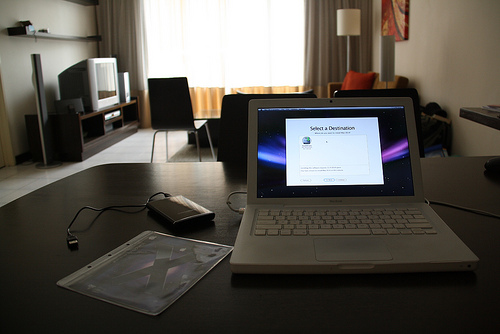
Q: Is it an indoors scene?
A: Yes, it is indoors.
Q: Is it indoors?
A: Yes, it is indoors.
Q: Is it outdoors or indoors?
A: It is indoors.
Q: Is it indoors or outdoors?
A: It is indoors.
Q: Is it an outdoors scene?
A: No, it is indoors.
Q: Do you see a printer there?
A: No, there are no printers.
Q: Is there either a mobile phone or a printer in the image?
A: No, there are no printers or cell phones.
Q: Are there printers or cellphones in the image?
A: No, there are no printers or cellphones.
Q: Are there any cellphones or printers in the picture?
A: No, there are no printers or cellphones.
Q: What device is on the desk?
A: The device is a hard drive.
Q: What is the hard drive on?
A: The hard drive is on the desk.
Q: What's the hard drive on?
A: The hard drive is on the desk.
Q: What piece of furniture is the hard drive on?
A: The hard drive is on the desk.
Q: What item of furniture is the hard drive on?
A: The hard drive is on the desk.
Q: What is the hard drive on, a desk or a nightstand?
A: The hard drive is on a desk.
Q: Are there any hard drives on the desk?
A: Yes, there is a hard drive on the desk.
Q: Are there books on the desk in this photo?
A: No, there is a hard drive on the desk.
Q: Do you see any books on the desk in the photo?
A: No, there is a hard drive on the desk.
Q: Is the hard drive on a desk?
A: Yes, the hard drive is on a desk.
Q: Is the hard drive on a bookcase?
A: No, the hard drive is on a desk.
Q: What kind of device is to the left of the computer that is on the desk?
A: The device is a hard drive.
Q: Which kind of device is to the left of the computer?
A: The device is a hard drive.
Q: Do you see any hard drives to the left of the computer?
A: Yes, there is a hard drive to the left of the computer.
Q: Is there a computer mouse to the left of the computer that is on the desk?
A: No, there is a hard drive to the left of the computer.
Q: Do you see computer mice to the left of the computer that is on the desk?
A: No, there is a hard drive to the left of the computer.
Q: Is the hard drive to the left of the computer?
A: Yes, the hard drive is to the left of the computer.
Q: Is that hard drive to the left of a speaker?
A: No, the hard drive is to the left of the computer.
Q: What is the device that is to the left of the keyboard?
A: The device is a hard drive.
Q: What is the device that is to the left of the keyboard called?
A: The device is a hard drive.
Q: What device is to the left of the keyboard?
A: The device is a hard drive.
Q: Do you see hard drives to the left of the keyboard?
A: Yes, there is a hard drive to the left of the keyboard.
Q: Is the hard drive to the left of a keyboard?
A: Yes, the hard drive is to the left of a keyboard.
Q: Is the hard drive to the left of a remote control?
A: No, the hard drive is to the left of a keyboard.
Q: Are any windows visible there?
A: Yes, there is a window.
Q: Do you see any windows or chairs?
A: Yes, there is a window.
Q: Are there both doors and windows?
A: No, there is a window but no doors.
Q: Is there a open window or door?
A: Yes, there is an open window.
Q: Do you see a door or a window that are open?
A: Yes, the window is open.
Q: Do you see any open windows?
A: Yes, there is an open window.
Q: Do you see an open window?
A: Yes, there is an open window.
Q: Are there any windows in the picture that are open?
A: Yes, there is a window that is open.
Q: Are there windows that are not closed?
A: Yes, there is a open window.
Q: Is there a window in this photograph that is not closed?
A: Yes, there is a open window.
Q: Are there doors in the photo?
A: No, there are no doors.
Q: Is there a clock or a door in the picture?
A: No, there are no doors or clocks.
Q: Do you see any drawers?
A: No, there are no drawers.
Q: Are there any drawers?
A: No, there are no drawers.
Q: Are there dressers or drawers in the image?
A: No, there are no drawers or dressers.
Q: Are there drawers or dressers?
A: No, there are no drawers or dressers.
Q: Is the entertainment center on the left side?
A: Yes, the entertainment center is on the left of the image.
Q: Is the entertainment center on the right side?
A: No, the entertainment center is on the left of the image.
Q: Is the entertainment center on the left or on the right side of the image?
A: The entertainment center is on the left of the image.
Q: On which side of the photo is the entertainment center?
A: The entertainment center is on the left of the image.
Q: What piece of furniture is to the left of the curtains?
A: The piece of furniture is an entertainment center.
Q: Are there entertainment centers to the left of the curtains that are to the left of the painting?
A: Yes, there is an entertainment center to the left of the curtains.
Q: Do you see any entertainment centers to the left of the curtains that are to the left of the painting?
A: Yes, there is an entertainment center to the left of the curtains.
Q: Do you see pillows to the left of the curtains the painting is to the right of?
A: No, there is an entertainment center to the left of the curtains.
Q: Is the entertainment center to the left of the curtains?
A: Yes, the entertainment center is to the left of the curtains.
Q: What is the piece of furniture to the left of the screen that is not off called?
A: The piece of furniture is an entertainment center.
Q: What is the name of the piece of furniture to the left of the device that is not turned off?
A: The piece of furniture is an entertainment center.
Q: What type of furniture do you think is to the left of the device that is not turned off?
A: The piece of furniture is an entertainment center.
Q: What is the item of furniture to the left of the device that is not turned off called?
A: The piece of furniture is an entertainment center.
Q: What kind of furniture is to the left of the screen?
A: The piece of furniture is an entertainment center.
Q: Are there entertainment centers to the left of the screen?
A: Yes, there is an entertainment center to the left of the screen.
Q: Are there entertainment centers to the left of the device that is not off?
A: Yes, there is an entertainment center to the left of the screen.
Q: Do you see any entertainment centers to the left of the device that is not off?
A: Yes, there is an entertainment center to the left of the screen.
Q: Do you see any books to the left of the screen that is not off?
A: No, there is an entertainment center to the left of the screen.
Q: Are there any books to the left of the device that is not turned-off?
A: No, there is an entertainment center to the left of the screen.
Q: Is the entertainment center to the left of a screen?
A: Yes, the entertainment center is to the left of a screen.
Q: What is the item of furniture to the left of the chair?
A: The piece of furniture is an entertainment center.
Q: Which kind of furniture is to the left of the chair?
A: The piece of furniture is an entertainment center.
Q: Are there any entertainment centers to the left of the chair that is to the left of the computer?
A: Yes, there is an entertainment center to the left of the chair.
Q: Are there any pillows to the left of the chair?
A: No, there is an entertainment center to the left of the chair.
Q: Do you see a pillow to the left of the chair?
A: No, there is an entertainment center to the left of the chair.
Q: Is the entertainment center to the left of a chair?
A: Yes, the entertainment center is to the left of a chair.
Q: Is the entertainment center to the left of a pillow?
A: No, the entertainment center is to the left of a chair.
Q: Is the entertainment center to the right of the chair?
A: No, the entertainment center is to the left of the chair.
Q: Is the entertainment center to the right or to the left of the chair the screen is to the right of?
A: The entertainment center is to the left of the chair.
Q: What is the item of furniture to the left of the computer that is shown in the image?
A: The piece of furniture is an entertainment center.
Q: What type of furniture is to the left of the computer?
A: The piece of furniture is an entertainment center.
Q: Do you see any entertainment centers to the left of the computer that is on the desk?
A: Yes, there is an entertainment center to the left of the computer.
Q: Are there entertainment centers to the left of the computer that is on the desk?
A: Yes, there is an entertainment center to the left of the computer.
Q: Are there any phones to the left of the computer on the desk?
A: No, there is an entertainment center to the left of the computer.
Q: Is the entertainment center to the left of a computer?
A: Yes, the entertainment center is to the left of a computer.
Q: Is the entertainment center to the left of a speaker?
A: No, the entertainment center is to the left of a computer.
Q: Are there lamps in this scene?
A: Yes, there is a lamp.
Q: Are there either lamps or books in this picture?
A: Yes, there is a lamp.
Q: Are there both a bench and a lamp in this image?
A: No, there is a lamp but no benches.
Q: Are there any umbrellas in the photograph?
A: No, there are no umbrellas.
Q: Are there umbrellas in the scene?
A: No, there are no umbrellas.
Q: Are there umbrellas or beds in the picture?
A: No, there are no umbrellas or beds.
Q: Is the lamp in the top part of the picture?
A: Yes, the lamp is in the top of the image.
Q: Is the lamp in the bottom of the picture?
A: No, the lamp is in the top of the image.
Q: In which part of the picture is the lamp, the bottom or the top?
A: The lamp is in the top of the image.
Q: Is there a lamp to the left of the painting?
A: Yes, there is a lamp to the left of the painting.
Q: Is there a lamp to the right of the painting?
A: No, the lamp is to the left of the painting.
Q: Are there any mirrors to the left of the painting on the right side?
A: No, there is a lamp to the left of the painting.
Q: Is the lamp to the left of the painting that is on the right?
A: Yes, the lamp is to the left of the painting.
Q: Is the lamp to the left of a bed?
A: No, the lamp is to the left of the painting.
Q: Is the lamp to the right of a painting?
A: No, the lamp is to the left of a painting.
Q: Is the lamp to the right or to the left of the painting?
A: The lamp is to the left of the painting.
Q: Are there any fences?
A: No, there are no fences.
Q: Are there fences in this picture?
A: No, there are no fences.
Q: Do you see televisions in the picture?
A: Yes, there is a television.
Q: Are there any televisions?
A: Yes, there is a television.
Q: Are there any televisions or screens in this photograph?
A: Yes, there is a television.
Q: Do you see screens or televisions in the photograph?
A: Yes, there is a television.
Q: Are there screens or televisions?
A: Yes, there is a television.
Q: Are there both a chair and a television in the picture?
A: Yes, there are both a television and a chair.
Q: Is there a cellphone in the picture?
A: No, there are no cell phones.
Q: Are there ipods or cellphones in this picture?
A: No, there are no cellphones or ipods.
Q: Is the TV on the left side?
A: Yes, the TV is on the left of the image.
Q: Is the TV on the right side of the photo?
A: No, the TV is on the left of the image.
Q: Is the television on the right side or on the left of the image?
A: The television is on the left of the image.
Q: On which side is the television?
A: The television is on the left of the image.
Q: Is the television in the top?
A: Yes, the television is in the top of the image.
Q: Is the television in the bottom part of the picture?
A: No, the television is in the top of the image.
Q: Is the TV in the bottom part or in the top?
A: The TV is in the top of the image.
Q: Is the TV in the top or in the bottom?
A: The TV is in the top of the image.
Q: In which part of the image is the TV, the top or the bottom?
A: The TV is in the top of the image.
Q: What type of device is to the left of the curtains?
A: The device is a television.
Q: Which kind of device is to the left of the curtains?
A: The device is a television.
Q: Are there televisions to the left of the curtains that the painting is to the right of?
A: Yes, there is a television to the left of the curtains.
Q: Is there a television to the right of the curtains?
A: No, the television is to the left of the curtains.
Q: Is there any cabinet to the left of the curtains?
A: No, there is a television to the left of the curtains.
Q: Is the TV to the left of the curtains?
A: Yes, the TV is to the left of the curtains.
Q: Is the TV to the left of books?
A: No, the TV is to the left of the curtains.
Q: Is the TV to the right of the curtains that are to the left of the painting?
A: No, the TV is to the left of the curtains.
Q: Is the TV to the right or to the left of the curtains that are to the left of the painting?
A: The TV is to the left of the curtains.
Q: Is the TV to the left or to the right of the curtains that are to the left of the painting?
A: The TV is to the left of the curtains.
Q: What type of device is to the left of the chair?
A: The device is a television.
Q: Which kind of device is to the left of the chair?
A: The device is a television.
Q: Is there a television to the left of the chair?
A: Yes, there is a television to the left of the chair.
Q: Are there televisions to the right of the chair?
A: No, the television is to the left of the chair.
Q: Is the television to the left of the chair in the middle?
A: Yes, the television is to the left of the chair.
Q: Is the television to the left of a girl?
A: No, the television is to the left of the chair.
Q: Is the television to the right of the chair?
A: No, the television is to the left of the chair.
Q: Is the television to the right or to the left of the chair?
A: The television is to the left of the chair.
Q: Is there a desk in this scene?
A: Yes, there is a desk.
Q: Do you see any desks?
A: Yes, there is a desk.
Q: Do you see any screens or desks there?
A: Yes, there is a desk.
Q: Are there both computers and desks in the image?
A: Yes, there are both a desk and a computer.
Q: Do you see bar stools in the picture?
A: No, there are no bar stools.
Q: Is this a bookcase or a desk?
A: This is a desk.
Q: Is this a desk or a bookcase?
A: This is a desk.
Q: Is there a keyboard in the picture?
A: Yes, there is a keyboard.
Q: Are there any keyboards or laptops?
A: Yes, there is a keyboard.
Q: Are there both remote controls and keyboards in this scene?
A: No, there is a keyboard but no remote controls.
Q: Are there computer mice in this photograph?
A: No, there are no computer mice.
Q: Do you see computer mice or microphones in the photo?
A: No, there are no computer mice or microphones.